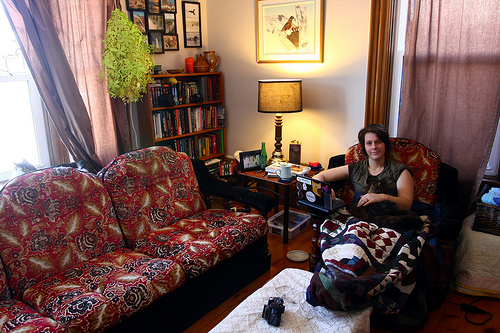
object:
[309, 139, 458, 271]
chair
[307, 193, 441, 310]
blanket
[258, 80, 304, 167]
standing lamp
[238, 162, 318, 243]
table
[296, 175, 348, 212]
laptop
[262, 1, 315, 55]
framed picture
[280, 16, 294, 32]
birds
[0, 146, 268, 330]
sofa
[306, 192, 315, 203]
sticker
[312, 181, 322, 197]
sticker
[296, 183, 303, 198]
sticker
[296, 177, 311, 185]
sticker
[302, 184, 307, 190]
sticker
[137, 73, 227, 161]
bookshelf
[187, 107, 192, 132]
books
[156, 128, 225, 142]
shelf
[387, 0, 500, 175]
window curtain shade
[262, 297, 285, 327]
camera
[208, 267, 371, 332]
stool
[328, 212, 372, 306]
legs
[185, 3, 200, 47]
picture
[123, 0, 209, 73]
wall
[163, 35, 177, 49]
picture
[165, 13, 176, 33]
picture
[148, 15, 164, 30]
picture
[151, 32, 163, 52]
picture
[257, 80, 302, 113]
shade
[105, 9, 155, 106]
tree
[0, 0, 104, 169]
window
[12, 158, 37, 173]
head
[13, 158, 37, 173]
cat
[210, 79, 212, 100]
books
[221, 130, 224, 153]
books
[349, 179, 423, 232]
cat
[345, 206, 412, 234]
lap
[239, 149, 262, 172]
picture frame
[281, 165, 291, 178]
cup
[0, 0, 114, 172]
curtain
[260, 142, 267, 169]
bottle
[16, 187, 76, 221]
crazy pattern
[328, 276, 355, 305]
feet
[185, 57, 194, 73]
candle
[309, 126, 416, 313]
lady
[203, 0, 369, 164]
wall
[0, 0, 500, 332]
living room